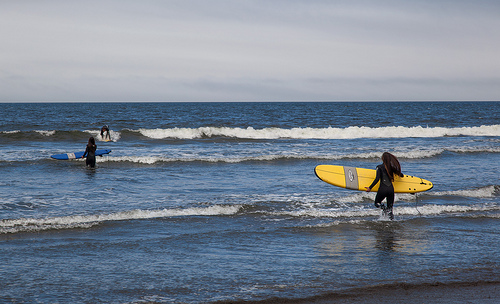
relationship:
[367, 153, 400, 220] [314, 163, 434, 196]
surfer holds surfboard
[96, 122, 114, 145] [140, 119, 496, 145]
surfer rides waves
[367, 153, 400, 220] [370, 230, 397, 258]
surfer has reflection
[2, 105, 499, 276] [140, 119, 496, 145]
ocean has waves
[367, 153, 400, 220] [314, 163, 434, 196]
surfer carrying surfboard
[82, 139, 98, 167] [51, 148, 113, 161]
surfer carrying surfboard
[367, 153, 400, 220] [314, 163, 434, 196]
surfer holding surfboard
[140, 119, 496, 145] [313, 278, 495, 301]
waves near beach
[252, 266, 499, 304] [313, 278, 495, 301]
beach on beach